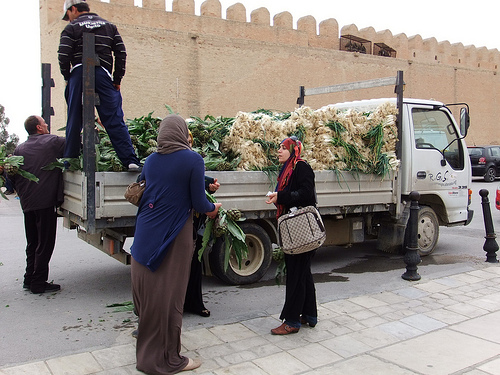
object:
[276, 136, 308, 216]
head scarf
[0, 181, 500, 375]
street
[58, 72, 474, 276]
truck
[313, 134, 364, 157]
plants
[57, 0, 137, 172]
man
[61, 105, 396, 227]
truck bed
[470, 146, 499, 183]
car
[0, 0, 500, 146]
wall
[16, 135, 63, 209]
jacket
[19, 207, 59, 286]
pants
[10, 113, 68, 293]
man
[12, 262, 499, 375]
pavement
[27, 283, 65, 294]
shoes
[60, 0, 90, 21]
baseball cap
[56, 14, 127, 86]
jacket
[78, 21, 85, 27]
lettering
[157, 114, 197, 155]
scarf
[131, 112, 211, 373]
lady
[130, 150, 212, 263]
sweater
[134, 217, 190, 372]
skirt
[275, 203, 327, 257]
bag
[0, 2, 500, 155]
building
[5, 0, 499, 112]
background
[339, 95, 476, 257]
front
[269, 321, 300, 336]
shoes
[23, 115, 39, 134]
hair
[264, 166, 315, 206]
arm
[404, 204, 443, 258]
wheel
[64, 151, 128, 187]
bed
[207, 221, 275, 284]
tire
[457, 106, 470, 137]
mirror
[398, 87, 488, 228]
side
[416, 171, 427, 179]
handle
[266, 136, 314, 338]
ladies